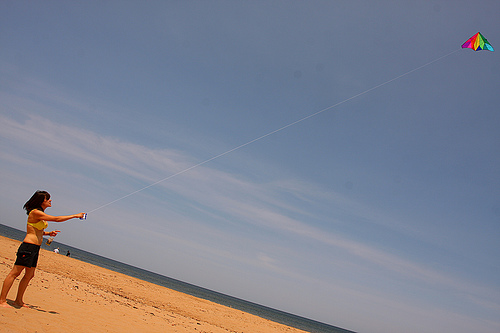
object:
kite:
[460, 30, 495, 53]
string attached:
[86, 44, 460, 206]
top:
[25, 218, 49, 235]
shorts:
[14, 241, 40, 266]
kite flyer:
[0, 190, 87, 309]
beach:
[56, 236, 353, 332]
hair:
[23, 189, 52, 210]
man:
[53, 243, 61, 255]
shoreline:
[73, 247, 312, 332]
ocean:
[71, 246, 358, 331]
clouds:
[0, 110, 199, 192]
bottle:
[45, 228, 57, 243]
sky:
[0, 1, 461, 190]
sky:
[137, 58, 499, 271]